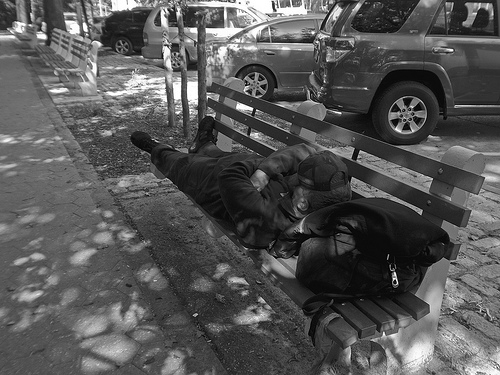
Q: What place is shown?
A: It is a street.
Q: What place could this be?
A: It is a street.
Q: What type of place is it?
A: It is a street.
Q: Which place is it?
A: It is a street.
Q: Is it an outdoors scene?
A: Yes, it is outdoors.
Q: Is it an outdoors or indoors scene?
A: It is outdoors.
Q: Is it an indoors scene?
A: No, it is outdoors.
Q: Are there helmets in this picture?
A: No, there are no helmets.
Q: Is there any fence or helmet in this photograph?
A: No, there are no helmets or fences.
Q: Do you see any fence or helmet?
A: No, there are no helmets or fences.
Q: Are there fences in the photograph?
A: No, there are no fences.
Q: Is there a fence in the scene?
A: No, there are no fences.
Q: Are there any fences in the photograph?
A: No, there are no fences.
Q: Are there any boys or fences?
A: No, there are no fences or boys.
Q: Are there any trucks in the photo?
A: No, there are no trucks.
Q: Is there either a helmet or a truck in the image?
A: No, there are no trucks or helmets.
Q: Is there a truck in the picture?
A: No, there are no trucks.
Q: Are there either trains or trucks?
A: No, there are no trucks or trains.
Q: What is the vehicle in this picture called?
A: The vehicle is a car.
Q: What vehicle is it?
A: The vehicle is a car.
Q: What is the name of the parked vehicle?
A: The vehicle is a car.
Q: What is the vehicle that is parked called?
A: The vehicle is a car.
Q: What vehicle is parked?
A: The vehicle is a car.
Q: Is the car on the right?
A: Yes, the car is on the right of the image.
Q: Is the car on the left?
A: No, the car is on the right of the image.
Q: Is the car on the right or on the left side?
A: The car is on the right of the image.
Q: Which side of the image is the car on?
A: The car is on the right of the image.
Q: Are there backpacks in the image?
A: Yes, there is a backpack.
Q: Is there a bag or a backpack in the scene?
A: Yes, there is a backpack.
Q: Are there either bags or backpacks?
A: Yes, there is a backpack.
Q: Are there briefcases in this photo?
A: No, there are no briefcases.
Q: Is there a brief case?
A: No, there are no briefcases.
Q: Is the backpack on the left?
A: No, the backpack is on the right of the image.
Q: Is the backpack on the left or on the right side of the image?
A: The backpack is on the right of the image.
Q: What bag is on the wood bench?
A: The bag is a backpack.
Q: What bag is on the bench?
A: The bag is a backpack.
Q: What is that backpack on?
A: The backpack is on the bench.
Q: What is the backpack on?
A: The backpack is on the bench.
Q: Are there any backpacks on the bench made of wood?
A: Yes, there is a backpack on the bench.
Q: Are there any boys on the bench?
A: No, there is a backpack on the bench.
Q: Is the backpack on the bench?
A: Yes, the backpack is on the bench.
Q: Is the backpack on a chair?
A: No, the backpack is on the bench.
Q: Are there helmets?
A: No, there are no helmets.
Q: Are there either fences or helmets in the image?
A: No, there are no helmets or fences.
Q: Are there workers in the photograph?
A: No, there are no workers.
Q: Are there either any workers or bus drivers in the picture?
A: No, there are no workers or bus drivers.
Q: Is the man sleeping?
A: Yes, the man is sleeping.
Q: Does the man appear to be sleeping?
A: Yes, the man is sleeping.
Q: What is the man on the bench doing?
A: The man is sleeping.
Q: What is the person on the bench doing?
A: The man is sleeping.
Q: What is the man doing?
A: The man is sleeping.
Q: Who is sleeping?
A: The man is sleeping.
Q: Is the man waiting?
A: No, the man is sleeping.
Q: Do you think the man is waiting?
A: No, the man is sleeping.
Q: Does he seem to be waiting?
A: No, the man is sleeping.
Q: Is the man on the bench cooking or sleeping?
A: The man is sleeping.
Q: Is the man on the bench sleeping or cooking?
A: The man is sleeping.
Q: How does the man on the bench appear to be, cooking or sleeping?
A: The man is sleeping.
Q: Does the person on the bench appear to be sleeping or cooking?
A: The man is sleeping.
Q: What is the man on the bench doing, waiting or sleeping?
A: The man is sleeping.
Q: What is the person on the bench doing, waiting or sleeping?
A: The man is sleeping.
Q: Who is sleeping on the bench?
A: The man is sleeping on the bench.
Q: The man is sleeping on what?
A: The man is sleeping on the bench.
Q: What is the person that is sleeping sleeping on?
A: The man is sleeping on the bench.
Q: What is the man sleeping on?
A: The man is sleeping on the bench.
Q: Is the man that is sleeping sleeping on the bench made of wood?
A: Yes, the man is sleeping on the bench.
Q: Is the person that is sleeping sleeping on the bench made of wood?
A: Yes, the man is sleeping on the bench.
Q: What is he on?
A: The man is on the bench.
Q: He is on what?
A: The man is on the bench.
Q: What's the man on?
A: The man is on the bench.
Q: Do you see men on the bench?
A: Yes, there is a man on the bench.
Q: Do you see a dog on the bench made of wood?
A: No, there is a man on the bench.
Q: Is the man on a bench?
A: Yes, the man is on a bench.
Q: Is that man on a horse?
A: No, the man is on a bench.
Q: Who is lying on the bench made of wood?
A: The man is lying on the bench.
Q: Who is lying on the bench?
A: The man is lying on the bench.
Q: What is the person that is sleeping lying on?
A: The man is lying on the bench.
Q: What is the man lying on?
A: The man is lying on the bench.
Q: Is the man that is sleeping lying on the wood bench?
A: Yes, the man is lying on the bench.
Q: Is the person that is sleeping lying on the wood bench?
A: Yes, the man is lying on the bench.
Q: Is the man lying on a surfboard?
A: No, the man is lying on the bench.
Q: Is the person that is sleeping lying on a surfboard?
A: No, the man is lying on the bench.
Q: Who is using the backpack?
A: The man is using the backpack.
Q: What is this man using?
A: The man is using a backpack.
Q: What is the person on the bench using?
A: The man is using a backpack.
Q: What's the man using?
A: The man is using a backpack.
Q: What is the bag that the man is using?
A: The bag is a backpack.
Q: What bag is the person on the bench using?
A: The man is using a backpack.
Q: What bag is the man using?
A: The man is using a backpack.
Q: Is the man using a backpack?
A: Yes, the man is using a backpack.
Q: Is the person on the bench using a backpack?
A: Yes, the man is using a backpack.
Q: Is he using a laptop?
A: No, the man is using a backpack.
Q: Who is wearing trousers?
A: The man is wearing trousers.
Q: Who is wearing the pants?
A: The man is wearing trousers.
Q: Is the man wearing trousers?
A: Yes, the man is wearing trousers.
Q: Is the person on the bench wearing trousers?
A: Yes, the man is wearing trousers.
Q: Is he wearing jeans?
A: No, the man is wearing trousers.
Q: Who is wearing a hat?
A: The man is wearing a hat.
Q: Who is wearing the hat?
A: The man is wearing a hat.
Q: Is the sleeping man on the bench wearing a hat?
A: Yes, the man is wearing a hat.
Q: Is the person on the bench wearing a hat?
A: Yes, the man is wearing a hat.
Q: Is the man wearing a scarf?
A: No, the man is wearing a hat.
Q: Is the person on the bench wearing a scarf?
A: No, the man is wearing a hat.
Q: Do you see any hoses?
A: No, there are no hoses.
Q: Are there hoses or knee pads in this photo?
A: No, there are no hoses or knee pads.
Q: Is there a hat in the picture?
A: Yes, there is a hat.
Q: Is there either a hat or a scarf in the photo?
A: Yes, there is a hat.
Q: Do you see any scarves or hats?
A: Yes, there is a hat.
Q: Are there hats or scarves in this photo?
A: Yes, there is a hat.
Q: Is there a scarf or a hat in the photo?
A: Yes, there is a hat.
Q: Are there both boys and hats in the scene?
A: No, there is a hat but no boys.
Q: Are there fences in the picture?
A: No, there are no fences.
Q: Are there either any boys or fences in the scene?
A: No, there are no fences or boys.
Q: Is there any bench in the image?
A: Yes, there is a bench.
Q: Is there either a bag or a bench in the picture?
A: Yes, there is a bench.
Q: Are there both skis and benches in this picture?
A: No, there is a bench but no skis.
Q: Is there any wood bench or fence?
A: Yes, there is a wood bench.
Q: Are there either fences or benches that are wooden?
A: Yes, the bench is wooden.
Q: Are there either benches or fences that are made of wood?
A: Yes, the bench is made of wood.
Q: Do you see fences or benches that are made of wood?
A: Yes, the bench is made of wood.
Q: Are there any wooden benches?
A: Yes, there is a wood bench.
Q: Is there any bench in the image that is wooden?
A: Yes, there is a bench that is wooden.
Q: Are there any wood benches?
A: Yes, there is a bench that is made of wood.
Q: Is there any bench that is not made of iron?
A: Yes, there is a bench that is made of wood.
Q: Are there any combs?
A: No, there are no combs.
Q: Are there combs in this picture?
A: No, there are no combs.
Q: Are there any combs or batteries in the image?
A: No, there are no combs or batteries.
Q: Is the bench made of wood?
A: Yes, the bench is made of wood.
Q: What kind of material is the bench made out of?
A: The bench is made of wood.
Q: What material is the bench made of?
A: The bench is made of wood.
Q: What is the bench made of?
A: The bench is made of wood.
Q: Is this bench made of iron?
A: No, the bench is made of wood.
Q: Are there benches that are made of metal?
A: No, there is a bench but it is made of wood.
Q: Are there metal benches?
A: No, there is a bench but it is made of wood.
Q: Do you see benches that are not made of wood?
A: No, there is a bench but it is made of wood.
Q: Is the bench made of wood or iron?
A: The bench is made of wood.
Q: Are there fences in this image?
A: No, there are no fences.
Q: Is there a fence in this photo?
A: No, there are no fences.